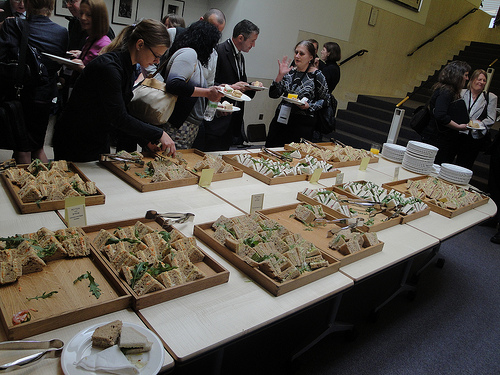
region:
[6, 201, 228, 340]
A BOX OF SANDWICHES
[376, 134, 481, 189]
THREE STACKS OF PLATES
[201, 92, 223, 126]
A BOTTLE OF WATER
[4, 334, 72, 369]
A PAIR OF METAL PRONGS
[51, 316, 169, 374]
A PLATE OF SANDWICHES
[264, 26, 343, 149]
A WOMAN HOLDING A PLATE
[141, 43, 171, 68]
A PAIR OF GLASSES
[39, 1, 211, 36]
PICTURES HANGING ON THE WALL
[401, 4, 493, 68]
A STAIRCASE RAIL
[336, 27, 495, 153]
A STAIRCASE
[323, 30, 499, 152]
There are stairs on the right.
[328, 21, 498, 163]
The stairs are carpeted.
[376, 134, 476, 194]
Four stacks on plates on table.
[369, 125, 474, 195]
The plates are all white.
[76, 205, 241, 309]
Sandwiches in wooden boxes.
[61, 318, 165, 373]
Sandwiches on a plate.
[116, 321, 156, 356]
Sandwich is triangular shaped.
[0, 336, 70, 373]
Tongs are laying on table.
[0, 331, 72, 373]
Tongs are next to plate.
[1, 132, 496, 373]
The tables are all white.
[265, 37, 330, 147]
mature woman talking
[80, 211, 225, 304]
tray full of triangle shaped sandwiches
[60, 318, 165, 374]
white plate with 2 sandwich halves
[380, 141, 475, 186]
three stacks of white plates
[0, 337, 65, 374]
silver tongs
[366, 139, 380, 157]
glass of orange juice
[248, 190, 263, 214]
little card saying kind of sandwiches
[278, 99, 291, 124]
id badge around woman's neck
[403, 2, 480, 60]
long railing for stairs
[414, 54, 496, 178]
2 women standing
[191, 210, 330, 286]
Box of sandwiches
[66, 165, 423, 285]
Table with boxes of sandwiches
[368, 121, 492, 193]
Three stacks of white plates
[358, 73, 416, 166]
Gray staircase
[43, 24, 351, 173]
Group of people eating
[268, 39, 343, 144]
Woman standing with a plate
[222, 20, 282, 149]
Man standing with a plate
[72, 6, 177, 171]
Woman with glasses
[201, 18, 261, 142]
Man in a suit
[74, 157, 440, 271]
Sandwiches laid out for people to eat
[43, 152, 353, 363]
white table with trays of food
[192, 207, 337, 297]
wooden tray full of sandwhiches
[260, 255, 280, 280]
triangle shaped sandwich in wooden tray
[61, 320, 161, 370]
round white ceramic plate on table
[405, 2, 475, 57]
black hand rail on stairs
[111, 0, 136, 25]
framed photo on wall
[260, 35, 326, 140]
older woman holding plate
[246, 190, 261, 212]
cardboard sign on table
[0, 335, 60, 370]
shiny silver metal tongs on table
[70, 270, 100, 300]
green leafy herb on tray